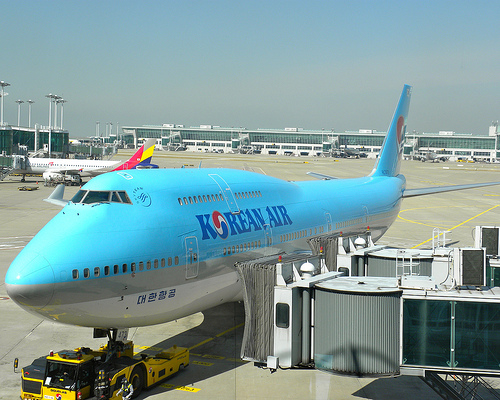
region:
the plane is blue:
[5, 79, 430, 324]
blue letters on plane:
[173, 198, 297, 255]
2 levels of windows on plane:
[31, 171, 361, 291]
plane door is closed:
[168, 231, 214, 282]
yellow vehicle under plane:
[9, 336, 200, 398]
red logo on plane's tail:
[382, 109, 412, 158]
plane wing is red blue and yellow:
[104, 133, 173, 180]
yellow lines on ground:
[392, 174, 498, 259]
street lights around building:
[0, 68, 98, 158]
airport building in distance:
[114, 110, 496, 173]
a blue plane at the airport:
[13, 142, 425, 330]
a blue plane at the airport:
[3, 50, 473, 395]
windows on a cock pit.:
[37, 173, 154, 235]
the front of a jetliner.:
[1, 158, 146, 360]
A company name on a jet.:
[183, 199, 303, 254]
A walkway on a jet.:
[274, 254, 498, 388]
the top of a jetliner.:
[80, 170, 321, 210]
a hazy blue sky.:
[1, 0, 489, 132]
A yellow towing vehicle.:
[6, 311, 202, 396]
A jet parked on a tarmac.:
[10, 112, 172, 190]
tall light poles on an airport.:
[47, 80, 78, 145]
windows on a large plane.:
[66, 170, 141, 213]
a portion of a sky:
[1, 0, 497, 79]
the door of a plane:
[180, 232, 209, 278]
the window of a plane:
[85, 188, 109, 204]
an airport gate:
[227, 255, 498, 380]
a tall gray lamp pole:
[43, 90, 58, 125]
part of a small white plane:
[20, 152, 112, 172]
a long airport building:
[129, 124, 498, 150]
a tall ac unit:
[457, 247, 487, 287]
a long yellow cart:
[20, 321, 192, 398]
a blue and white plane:
[36, 81, 488, 346]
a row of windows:
[69, 253, 189, 283]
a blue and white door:
[186, 231, 198, 284]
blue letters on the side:
[139, 286, 179, 308]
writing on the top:
[197, 207, 294, 236]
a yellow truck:
[15, 342, 197, 394]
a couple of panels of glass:
[404, 306, 499, 363]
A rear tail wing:
[369, 83, 426, 185]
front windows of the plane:
[72, 188, 129, 207]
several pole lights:
[42, 95, 63, 160]